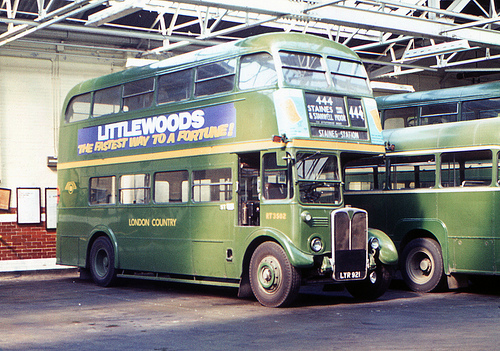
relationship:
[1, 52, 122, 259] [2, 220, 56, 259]
wall has bricked area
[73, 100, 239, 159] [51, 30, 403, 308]
ad on side of bus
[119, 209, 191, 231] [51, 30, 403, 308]
words written on bus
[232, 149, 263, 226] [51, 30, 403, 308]
window on side of bus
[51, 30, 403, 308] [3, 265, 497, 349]
bus in parking lot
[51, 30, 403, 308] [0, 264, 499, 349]
bus sitting in lot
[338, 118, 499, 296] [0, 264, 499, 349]
bus sitting in lot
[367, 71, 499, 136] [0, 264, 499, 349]
bus sitting in lot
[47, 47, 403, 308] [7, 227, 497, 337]
bus in parking lot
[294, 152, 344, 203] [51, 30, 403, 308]
windshield on bus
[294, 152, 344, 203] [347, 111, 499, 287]
windshield on bus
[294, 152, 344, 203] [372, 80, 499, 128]
windshield on bus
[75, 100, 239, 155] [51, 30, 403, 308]
ad on bus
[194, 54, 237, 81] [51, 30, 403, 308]
window on bus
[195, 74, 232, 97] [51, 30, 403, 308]
window on bus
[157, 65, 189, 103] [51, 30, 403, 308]
window on bus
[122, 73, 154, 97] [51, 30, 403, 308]
window on bus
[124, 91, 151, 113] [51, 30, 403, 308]
window on bus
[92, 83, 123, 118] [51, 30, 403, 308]
window on bus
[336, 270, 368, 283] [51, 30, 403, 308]
numbers on bus